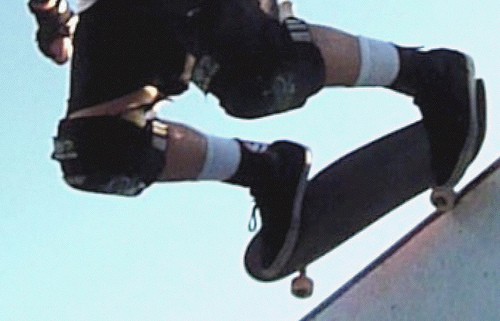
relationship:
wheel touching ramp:
[425, 179, 462, 217] [287, 152, 498, 319]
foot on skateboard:
[256, 140, 309, 277] [234, 78, 490, 298]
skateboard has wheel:
[234, 78, 490, 298] [430, 183, 460, 216]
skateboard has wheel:
[234, 78, 490, 298] [290, 276, 316, 297]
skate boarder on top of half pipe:
[27, 2, 487, 297] [312, 167, 494, 317]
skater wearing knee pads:
[26, 0, 477, 281] [57, 14, 328, 197]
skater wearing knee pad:
[26, 0, 477, 281] [45, 140, 117, 182]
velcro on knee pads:
[279, 14, 326, 110] [183, 14, 328, 129]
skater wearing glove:
[26, 0, 477, 280] [28, 6, 66, 76]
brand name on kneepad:
[107, 182, 143, 203] [55, 109, 205, 202]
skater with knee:
[26, 0, 477, 280] [56, 114, 151, 199]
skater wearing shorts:
[26, 0, 477, 280] [67, 1, 259, 115]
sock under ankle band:
[354, 33, 407, 84] [396, 36, 427, 95]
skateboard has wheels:
[234, 78, 490, 298] [427, 186, 458, 211]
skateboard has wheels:
[234, 78, 490, 298] [290, 273, 316, 298]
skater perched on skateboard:
[26, 0, 477, 281] [240, 77, 490, 303]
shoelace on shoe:
[247, 205, 257, 233] [411, 43, 477, 191]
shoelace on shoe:
[247, 205, 257, 233] [252, 138, 311, 276]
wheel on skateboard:
[290, 276, 315, 297] [234, 78, 490, 298]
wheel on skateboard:
[430, 185, 462, 211] [234, 78, 490, 298]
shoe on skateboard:
[411, 43, 477, 191] [234, 78, 490, 298]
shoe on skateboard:
[246, 136, 312, 276] [234, 78, 490, 298]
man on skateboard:
[19, 0, 476, 278] [234, 78, 490, 298]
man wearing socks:
[19, 0, 476, 278] [200, 35, 409, 182]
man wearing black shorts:
[19, 0, 476, 278] [61, 1, 236, 116]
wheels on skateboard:
[290, 182, 460, 297] [234, 78, 490, 298]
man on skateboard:
[43, 7, 480, 278] [234, 78, 490, 298]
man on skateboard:
[25, 0, 477, 267] [234, 78, 490, 298]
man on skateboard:
[19, 0, 476, 299] [234, 78, 490, 298]